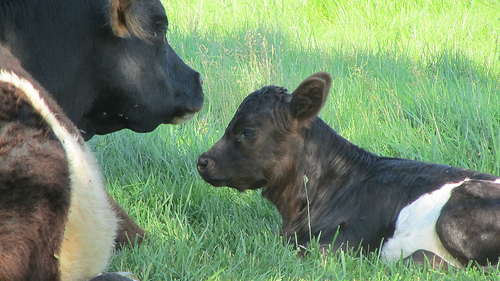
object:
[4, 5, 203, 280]
cow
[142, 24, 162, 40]
eye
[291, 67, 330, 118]
ears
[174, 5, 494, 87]
grass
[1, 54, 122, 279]
torso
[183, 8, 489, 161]
field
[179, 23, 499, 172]
shadow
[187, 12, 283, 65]
weeds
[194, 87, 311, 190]
head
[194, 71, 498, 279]
calf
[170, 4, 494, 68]
sunlight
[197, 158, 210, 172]
nostril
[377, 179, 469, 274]
spots